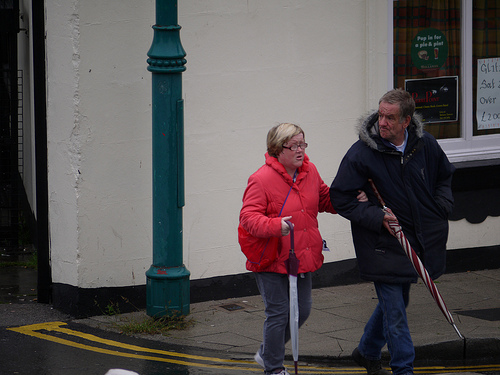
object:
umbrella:
[360, 172, 466, 345]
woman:
[247, 119, 334, 372]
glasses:
[283, 143, 310, 152]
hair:
[266, 122, 305, 159]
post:
[141, 3, 191, 316]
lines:
[50, 323, 219, 363]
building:
[38, 1, 496, 320]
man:
[325, 88, 459, 374]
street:
[14, 325, 495, 374]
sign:
[474, 54, 498, 137]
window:
[391, 0, 467, 141]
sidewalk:
[77, 264, 499, 364]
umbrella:
[283, 219, 302, 371]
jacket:
[235, 152, 340, 275]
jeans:
[358, 276, 417, 366]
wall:
[41, 0, 500, 306]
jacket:
[326, 107, 458, 283]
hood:
[354, 107, 379, 150]